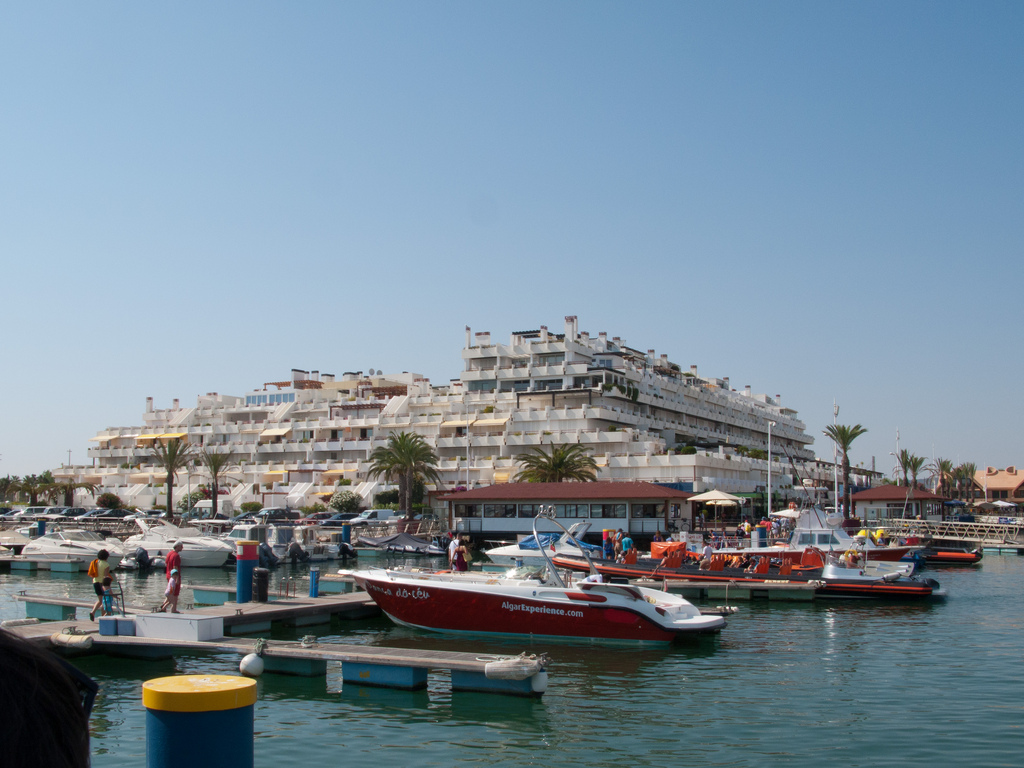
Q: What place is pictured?
A: It is a marina.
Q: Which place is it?
A: It is a marina.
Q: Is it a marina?
A: Yes, it is a marina.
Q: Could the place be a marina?
A: Yes, it is a marina.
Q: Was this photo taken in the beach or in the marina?
A: It was taken at the marina.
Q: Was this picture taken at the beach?
A: No, the picture was taken in the marina.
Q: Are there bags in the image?
A: No, there are no bags.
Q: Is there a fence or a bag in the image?
A: No, there are no bags or fences.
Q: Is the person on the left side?
A: Yes, the person is on the left of the image.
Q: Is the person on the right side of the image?
A: No, the person is on the left of the image.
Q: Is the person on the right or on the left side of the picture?
A: The person is on the left of the image.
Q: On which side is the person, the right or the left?
A: The person is on the left of the image.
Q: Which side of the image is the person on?
A: The person is on the left of the image.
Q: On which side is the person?
A: The person is on the left of the image.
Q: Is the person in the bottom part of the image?
A: Yes, the person is in the bottom of the image.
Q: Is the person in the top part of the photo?
A: No, the person is in the bottom of the image.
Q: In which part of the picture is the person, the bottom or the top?
A: The person is in the bottom of the image.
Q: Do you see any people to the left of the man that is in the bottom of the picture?
A: Yes, there is a person to the left of the man.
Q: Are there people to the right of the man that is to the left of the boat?
A: No, the person is to the left of the man.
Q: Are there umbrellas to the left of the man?
A: No, there is a person to the left of the man.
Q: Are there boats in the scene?
A: Yes, there is a boat.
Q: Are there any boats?
A: Yes, there is a boat.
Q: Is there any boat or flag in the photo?
A: Yes, there is a boat.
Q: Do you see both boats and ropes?
A: No, there is a boat but no ropes.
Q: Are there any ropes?
A: No, there are no ropes.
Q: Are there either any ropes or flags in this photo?
A: No, there are no ropes or flags.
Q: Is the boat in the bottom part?
A: Yes, the boat is in the bottom of the image.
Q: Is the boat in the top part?
A: No, the boat is in the bottom of the image.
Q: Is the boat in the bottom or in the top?
A: The boat is in the bottom of the image.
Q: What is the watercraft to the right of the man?
A: The watercraft is a boat.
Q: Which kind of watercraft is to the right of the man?
A: The watercraft is a boat.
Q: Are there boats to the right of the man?
A: Yes, there is a boat to the right of the man.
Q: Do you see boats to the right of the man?
A: Yes, there is a boat to the right of the man.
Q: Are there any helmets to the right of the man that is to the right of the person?
A: No, there is a boat to the right of the man.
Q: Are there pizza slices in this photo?
A: No, there are no pizza slices.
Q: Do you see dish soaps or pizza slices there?
A: No, there are no pizza slices or dish soaps.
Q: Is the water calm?
A: Yes, the water is calm.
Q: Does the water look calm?
A: Yes, the water is calm.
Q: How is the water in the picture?
A: The water is calm.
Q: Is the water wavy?
A: No, the water is calm.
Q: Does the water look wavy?
A: No, the water is calm.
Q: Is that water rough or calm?
A: The water is calm.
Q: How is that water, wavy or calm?
A: The water is calm.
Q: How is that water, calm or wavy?
A: The water is calm.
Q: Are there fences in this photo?
A: No, there are no fences.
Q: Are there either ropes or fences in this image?
A: No, there are no ropes or fences.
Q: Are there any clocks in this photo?
A: No, there are no clocks.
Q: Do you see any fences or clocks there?
A: No, there are no clocks or fences.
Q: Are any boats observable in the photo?
A: Yes, there is a boat.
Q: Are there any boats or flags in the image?
A: Yes, there is a boat.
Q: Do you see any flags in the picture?
A: No, there are no flags.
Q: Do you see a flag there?
A: No, there are no flags.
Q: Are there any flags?
A: No, there are no flags.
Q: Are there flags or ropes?
A: No, there are no flags or ropes.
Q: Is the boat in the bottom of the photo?
A: Yes, the boat is in the bottom of the image.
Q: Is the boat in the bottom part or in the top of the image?
A: The boat is in the bottom of the image.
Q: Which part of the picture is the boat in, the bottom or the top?
A: The boat is in the bottom of the image.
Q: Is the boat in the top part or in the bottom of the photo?
A: The boat is in the bottom of the image.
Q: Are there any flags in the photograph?
A: No, there are no flags.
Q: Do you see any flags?
A: No, there are no flags.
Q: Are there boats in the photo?
A: Yes, there is a boat.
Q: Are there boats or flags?
A: Yes, there is a boat.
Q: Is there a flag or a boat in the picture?
A: Yes, there is a boat.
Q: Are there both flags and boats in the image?
A: No, there is a boat but no flags.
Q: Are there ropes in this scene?
A: No, there are no ropes.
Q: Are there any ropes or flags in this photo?
A: No, there are no ropes or flags.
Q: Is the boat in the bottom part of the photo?
A: Yes, the boat is in the bottom of the image.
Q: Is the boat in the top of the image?
A: No, the boat is in the bottom of the image.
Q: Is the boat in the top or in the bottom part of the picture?
A: The boat is in the bottom of the image.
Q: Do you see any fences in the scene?
A: No, there are no fences.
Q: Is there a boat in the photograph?
A: Yes, there is a boat.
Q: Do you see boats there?
A: Yes, there is a boat.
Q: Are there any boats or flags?
A: Yes, there is a boat.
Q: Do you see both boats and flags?
A: No, there is a boat but no flags.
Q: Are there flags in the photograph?
A: No, there are no flags.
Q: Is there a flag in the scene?
A: No, there are no flags.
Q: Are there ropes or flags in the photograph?
A: No, there are no flags or ropes.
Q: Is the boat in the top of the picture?
A: No, the boat is in the bottom of the image.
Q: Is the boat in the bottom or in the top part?
A: The boat is in the bottom of the image.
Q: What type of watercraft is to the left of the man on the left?
A: The watercraft is a boat.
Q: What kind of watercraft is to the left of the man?
A: The watercraft is a boat.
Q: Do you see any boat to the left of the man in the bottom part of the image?
A: Yes, there is a boat to the left of the man.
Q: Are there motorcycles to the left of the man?
A: No, there is a boat to the left of the man.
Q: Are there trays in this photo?
A: No, there are no trays.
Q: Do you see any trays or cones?
A: No, there are no trays or cones.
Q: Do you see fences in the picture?
A: No, there are no fences.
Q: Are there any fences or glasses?
A: No, there are no fences or glasses.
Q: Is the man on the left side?
A: Yes, the man is on the left of the image.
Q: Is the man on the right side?
A: No, the man is on the left of the image.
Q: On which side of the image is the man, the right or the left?
A: The man is on the left of the image.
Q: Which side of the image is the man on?
A: The man is on the left of the image.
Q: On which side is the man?
A: The man is on the left of the image.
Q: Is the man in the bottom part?
A: Yes, the man is in the bottom of the image.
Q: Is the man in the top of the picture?
A: No, the man is in the bottom of the image.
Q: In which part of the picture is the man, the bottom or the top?
A: The man is in the bottom of the image.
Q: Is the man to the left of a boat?
A: Yes, the man is to the left of a boat.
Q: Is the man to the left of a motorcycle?
A: No, the man is to the left of a boat.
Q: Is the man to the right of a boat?
A: Yes, the man is to the right of a boat.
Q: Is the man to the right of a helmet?
A: No, the man is to the right of a boat.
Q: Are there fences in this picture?
A: No, there are no fences.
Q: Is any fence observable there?
A: No, there are no fences.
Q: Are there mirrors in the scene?
A: No, there are no mirrors.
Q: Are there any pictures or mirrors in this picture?
A: No, there are no mirrors or pictures.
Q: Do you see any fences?
A: No, there are no fences.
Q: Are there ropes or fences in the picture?
A: No, there are no fences or ropes.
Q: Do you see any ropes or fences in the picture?
A: No, there are no fences or ropes.